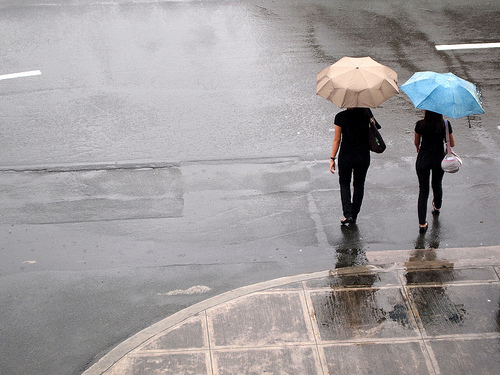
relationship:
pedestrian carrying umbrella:
[414, 110, 455, 231] [400, 70, 486, 119]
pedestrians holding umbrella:
[330, 107, 382, 225] [309, 25, 401, 120]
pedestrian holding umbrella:
[414, 110, 455, 231] [399, 63, 488, 131]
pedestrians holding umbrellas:
[330, 107, 382, 225] [294, 25, 471, 126]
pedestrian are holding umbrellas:
[414, 110, 455, 231] [309, 42, 491, 112]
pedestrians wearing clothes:
[330, 107, 382, 225] [334, 109, 381, 217]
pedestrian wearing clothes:
[414, 110, 455, 231] [411, 118, 452, 223]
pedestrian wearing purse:
[414, 110, 455, 231] [438, 118, 464, 175]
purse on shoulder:
[438, 118, 464, 175] [438, 119, 454, 139]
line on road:
[431, 37, 496, 59] [4, 6, 496, 372]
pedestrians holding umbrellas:
[323, 109, 475, 252] [323, 98, 363, 108]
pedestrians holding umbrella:
[330, 107, 382, 225] [312, 54, 399, 106]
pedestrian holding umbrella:
[403, 70, 483, 230] [400, 70, 481, 119]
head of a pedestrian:
[423, 109, 444, 126] [414, 110, 455, 231]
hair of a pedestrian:
[424, 111, 444, 131] [414, 110, 455, 231]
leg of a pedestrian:
[415, 165, 432, 229] [414, 110, 455, 231]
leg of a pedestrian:
[430, 168, 443, 214] [414, 110, 455, 231]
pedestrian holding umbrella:
[414, 110, 455, 231] [400, 70, 481, 119]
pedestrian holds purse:
[414, 110, 455, 231] [439, 119, 462, 173]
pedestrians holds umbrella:
[330, 107, 382, 225] [318, 50, 398, 107]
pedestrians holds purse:
[330, 107, 382, 225] [364, 107, 387, 153]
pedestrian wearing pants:
[414, 110, 455, 231] [412, 150, 446, 220]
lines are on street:
[2, 56, 42, 86] [0, 0, 499, 374]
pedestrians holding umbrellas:
[330, 107, 382, 225] [315, 51, 483, 125]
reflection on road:
[302, 233, 482, 349] [4, 6, 496, 372]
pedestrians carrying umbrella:
[330, 107, 382, 225] [307, 45, 414, 115]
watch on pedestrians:
[327, 153, 340, 160] [330, 107, 382, 225]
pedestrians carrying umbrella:
[330, 107, 382, 225] [301, 42, 405, 107]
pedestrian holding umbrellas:
[414, 110, 455, 231] [315, 51, 483, 125]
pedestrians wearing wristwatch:
[330, 107, 382, 225] [326, 151, 339, 163]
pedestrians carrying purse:
[330, 107, 382, 225] [359, 107, 388, 156]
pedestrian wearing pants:
[414, 110, 455, 231] [411, 153, 445, 231]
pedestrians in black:
[330, 107, 382, 225] [333, 107, 380, 219]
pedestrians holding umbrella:
[330, 107, 382, 225] [311, 52, 401, 112]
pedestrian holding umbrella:
[414, 110, 455, 231] [396, 67, 488, 122]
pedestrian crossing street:
[414, 110, 455, 231] [5, 2, 493, 372]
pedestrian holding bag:
[414, 110, 455, 231] [439, 114, 467, 176]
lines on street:
[0, 69, 43, 81] [5, 2, 493, 372]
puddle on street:
[293, 239, 365, 272] [5, 2, 493, 372]